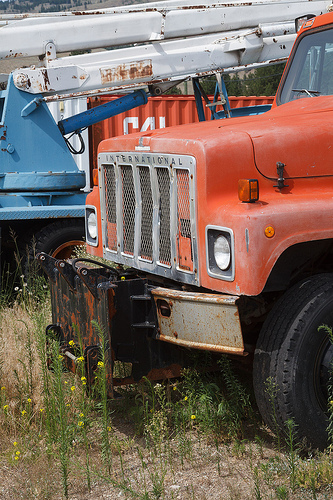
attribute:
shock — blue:
[59, 87, 147, 139]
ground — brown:
[0, 304, 331, 497]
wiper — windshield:
[197, 88, 243, 124]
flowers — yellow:
[96, 360, 104, 369]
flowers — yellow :
[30, 324, 152, 449]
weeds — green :
[6, 298, 225, 497]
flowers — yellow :
[54, 334, 103, 454]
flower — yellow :
[96, 359, 107, 370]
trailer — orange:
[84, 92, 277, 189]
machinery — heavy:
[23, 241, 154, 417]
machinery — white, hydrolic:
[11, 4, 261, 83]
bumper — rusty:
[133, 272, 258, 368]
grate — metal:
[91, 150, 211, 268]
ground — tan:
[116, 423, 232, 489]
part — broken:
[132, 275, 254, 365]